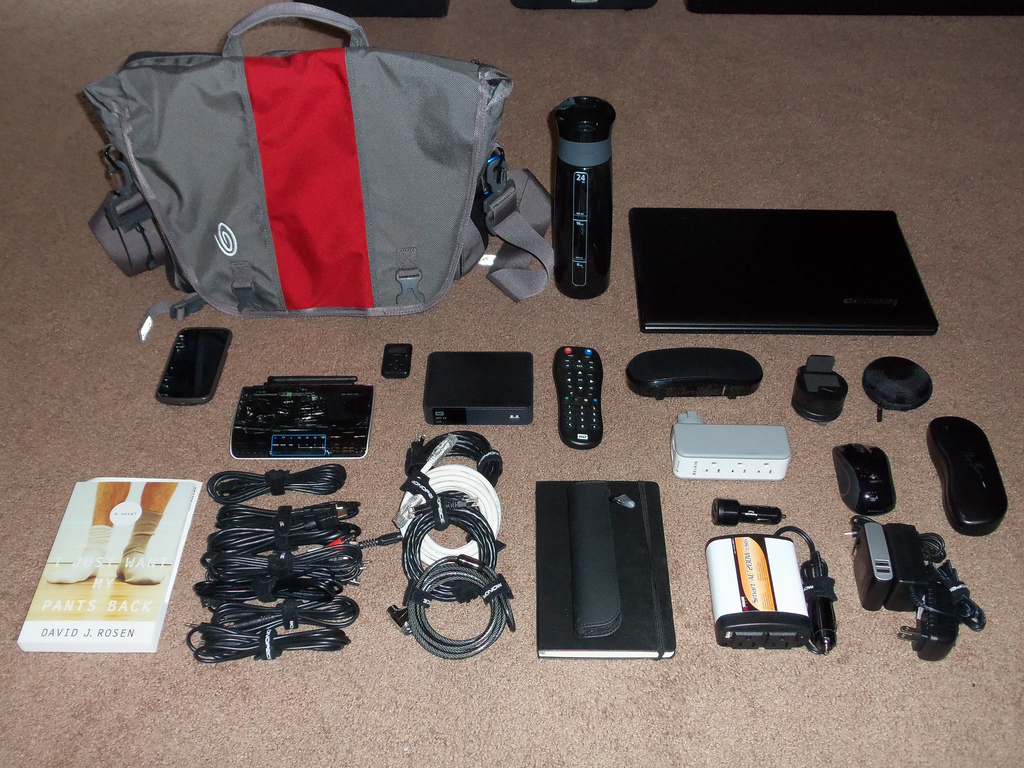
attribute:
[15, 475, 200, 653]
book — white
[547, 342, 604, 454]
remote — black  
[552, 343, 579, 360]
button — red  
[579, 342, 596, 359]
button — blue  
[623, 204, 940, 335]
laptop — black, rectangle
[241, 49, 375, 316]
stripe — thick, red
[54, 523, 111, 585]
sock — white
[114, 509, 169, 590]
sock — white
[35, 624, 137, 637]
name — David J. Rosen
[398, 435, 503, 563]
cord — rolled up, white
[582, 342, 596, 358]
button — round, blue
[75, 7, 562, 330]
bag — grey